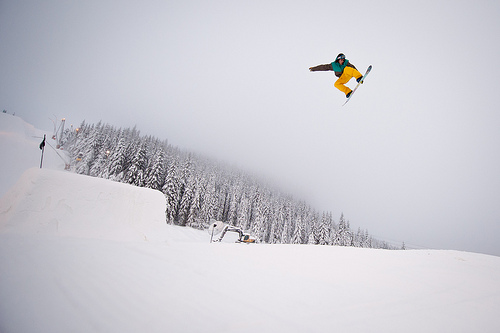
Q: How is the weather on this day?
A: It is foggy.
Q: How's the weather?
A: It is foggy.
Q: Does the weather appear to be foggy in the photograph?
A: Yes, it is foggy.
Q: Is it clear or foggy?
A: It is foggy.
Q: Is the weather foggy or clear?
A: It is foggy.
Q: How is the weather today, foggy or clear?
A: It is foggy.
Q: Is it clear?
A: No, it is foggy.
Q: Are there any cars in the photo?
A: No, there are no cars.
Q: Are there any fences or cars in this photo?
A: No, there are no cars or fences.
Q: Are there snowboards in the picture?
A: Yes, there is a snowboard.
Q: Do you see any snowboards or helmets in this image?
A: Yes, there is a snowboard.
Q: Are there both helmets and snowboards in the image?
A: Yes, there are both a snowboard and a helmet.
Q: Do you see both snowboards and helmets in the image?
A: Yes, there are both a snowboard and a helmet.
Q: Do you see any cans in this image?
A: No, there are no cans.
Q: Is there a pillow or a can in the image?
A: No, there are no cans or pillows.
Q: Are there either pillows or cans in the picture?
A: No, there are no cans or pillows.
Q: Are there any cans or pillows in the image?
A: No, there are no cans or pillows.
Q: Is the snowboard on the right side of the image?
A: Yes, the snowboard is on the right of the image.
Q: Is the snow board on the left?
A: No, the snow board is on the right of the image.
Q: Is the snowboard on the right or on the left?
A: The snowboard is on the right of the image.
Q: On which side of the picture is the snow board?
A: The snow board is on the right of the image.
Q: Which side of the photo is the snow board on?
A: The snow board is on the right of the image.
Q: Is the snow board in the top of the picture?
A: Yes, the snow board is in the top of the image.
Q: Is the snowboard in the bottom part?
A: No, the snowboard is in the top of the image.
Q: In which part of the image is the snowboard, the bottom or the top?
A: The snowboard is in the top of the image.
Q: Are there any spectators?
A: No, there are no spectators.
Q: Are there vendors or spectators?
A: No, there are no spectators or vendors.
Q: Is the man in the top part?
A: Yes, the man is in the top of the image.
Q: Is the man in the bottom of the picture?
A: No, the man is in the top of the image.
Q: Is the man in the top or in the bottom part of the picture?
A: The man is in the top of the image.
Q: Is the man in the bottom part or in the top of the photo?
A: The man is in the top of the image.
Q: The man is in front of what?
A: The man is in front of the trees.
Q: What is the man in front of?
A: The man is in front of the trees.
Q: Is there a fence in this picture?
A: No, there are no fences.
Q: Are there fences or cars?
A: No, there are no fences or cars.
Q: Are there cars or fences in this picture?
A: No, there are no fences or cars.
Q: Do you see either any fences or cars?
A: No, there are no fences or cars.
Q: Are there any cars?
A: No, there are no cars.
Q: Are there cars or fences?
A: No, there are no cars or fences.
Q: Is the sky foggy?
A: Yes, the sky is foggy.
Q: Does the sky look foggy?
A: Yes, the sky is foggy.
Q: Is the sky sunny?
A: No, the sky is foggy.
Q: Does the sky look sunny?
A: No, the sky is foggy.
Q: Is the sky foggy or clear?
A: The sky is foggy.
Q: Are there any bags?
A: No, there are no bags.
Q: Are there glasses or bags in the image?
A: No, there are no bags or glasses.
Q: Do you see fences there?
A: No, there are no fences.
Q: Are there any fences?
A: No, there are no fences.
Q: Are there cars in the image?
A: No, there are no cars.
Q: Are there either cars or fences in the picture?
A: No, there are no cars or fences.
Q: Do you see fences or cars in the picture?
A: No, there are no cars or fences.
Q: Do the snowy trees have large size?
A: Yes, the trees are large.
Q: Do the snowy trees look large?
A: Yes, the trees are large.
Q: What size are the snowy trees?
A: The trees are large.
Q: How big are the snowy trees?
A: The trees are large.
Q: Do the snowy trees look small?
A: No, the trees are large.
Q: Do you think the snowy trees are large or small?
A: The trees are large.